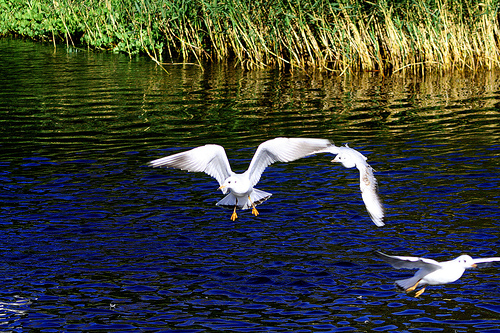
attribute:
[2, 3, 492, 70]
grass — wilde, green grass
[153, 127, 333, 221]
birds — white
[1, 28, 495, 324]
water — deep blue, extremely blue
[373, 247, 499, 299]
dove — white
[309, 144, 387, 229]
dove — white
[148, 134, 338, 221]
dove — white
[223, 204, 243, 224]
leg — orange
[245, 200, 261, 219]
leg — orange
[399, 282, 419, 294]
leg — orange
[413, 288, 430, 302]
leg — orange